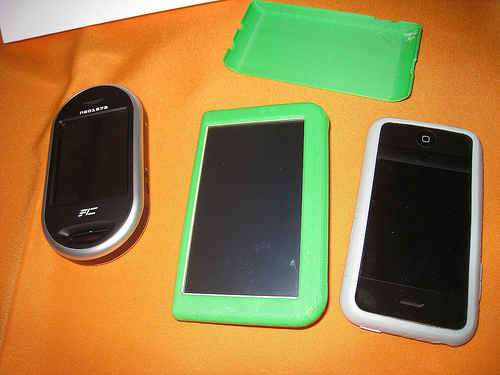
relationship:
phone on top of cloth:
[41, 83, 151, 263] [2, 2, 496, 373]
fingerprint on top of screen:
[289, 256, 298, 275] [181, 113, 307, 306]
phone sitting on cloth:
[41, 83, 151, 263] [2, 2, 496, 373]